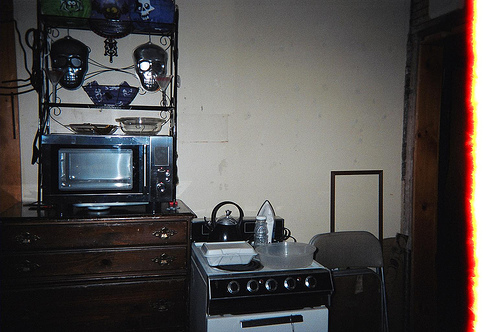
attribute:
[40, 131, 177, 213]
microwave — black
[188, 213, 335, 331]
oven — small, white, black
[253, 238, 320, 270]
container — clear, large,  foam, for food, plastic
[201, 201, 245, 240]
tea pot — black, silver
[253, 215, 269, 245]
bottle — clear, plastic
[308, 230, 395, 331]
chair — brown, grey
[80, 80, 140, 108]
bowl — blue, large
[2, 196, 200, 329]
drawer — wooden, dark, brown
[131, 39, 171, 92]
skull pan — silver,  metal,  skull, metal, shiny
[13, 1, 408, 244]
wall — white,  white,  visible, light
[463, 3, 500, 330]
burn line —  burn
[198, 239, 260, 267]
takeout box — white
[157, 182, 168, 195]
knob — black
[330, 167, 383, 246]
frame —  black,  rectagular, for picture